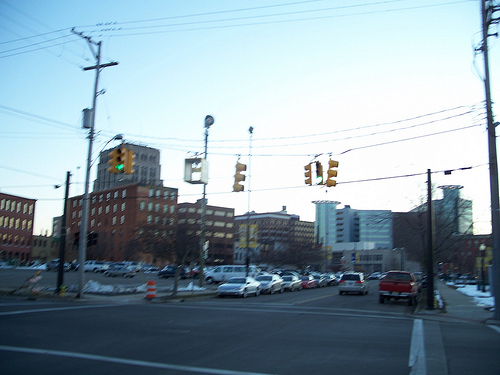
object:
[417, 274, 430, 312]
curb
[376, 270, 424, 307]
truck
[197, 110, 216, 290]
light pole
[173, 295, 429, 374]
lines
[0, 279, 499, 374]
road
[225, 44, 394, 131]
clouds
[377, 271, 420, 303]
red truck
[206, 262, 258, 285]
van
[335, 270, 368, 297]
car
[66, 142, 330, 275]
buildings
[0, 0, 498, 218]
clouds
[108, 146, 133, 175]
light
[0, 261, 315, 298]
parking lot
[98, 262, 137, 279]
cars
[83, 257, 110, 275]
cars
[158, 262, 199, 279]
cars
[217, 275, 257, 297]
car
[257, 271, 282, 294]
car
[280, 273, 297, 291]
car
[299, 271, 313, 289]
car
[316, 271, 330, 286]
car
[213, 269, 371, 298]
cars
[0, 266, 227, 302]
sidewalk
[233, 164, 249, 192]
signal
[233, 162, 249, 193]
traffic signal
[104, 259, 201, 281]
cars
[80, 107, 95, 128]
box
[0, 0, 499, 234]
blue sky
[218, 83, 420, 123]
white cloud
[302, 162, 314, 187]
light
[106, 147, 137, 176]
traffic light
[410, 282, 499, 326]
sidewalk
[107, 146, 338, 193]
traffic lights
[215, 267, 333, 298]
cars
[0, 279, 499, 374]
street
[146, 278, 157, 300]
barrel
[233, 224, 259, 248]
sign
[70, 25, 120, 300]
pole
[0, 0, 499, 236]
sky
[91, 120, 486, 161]
wire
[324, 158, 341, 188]
light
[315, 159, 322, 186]
light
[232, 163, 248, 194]
light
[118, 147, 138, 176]
light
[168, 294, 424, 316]
line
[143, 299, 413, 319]
line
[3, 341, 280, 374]
line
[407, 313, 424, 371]
line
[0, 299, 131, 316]
line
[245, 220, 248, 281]
pole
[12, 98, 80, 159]
clouds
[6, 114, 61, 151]
white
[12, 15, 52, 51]
blue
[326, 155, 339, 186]
signal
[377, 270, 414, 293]
red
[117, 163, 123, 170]
green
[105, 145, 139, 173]
above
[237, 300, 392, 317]
line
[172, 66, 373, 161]
clear